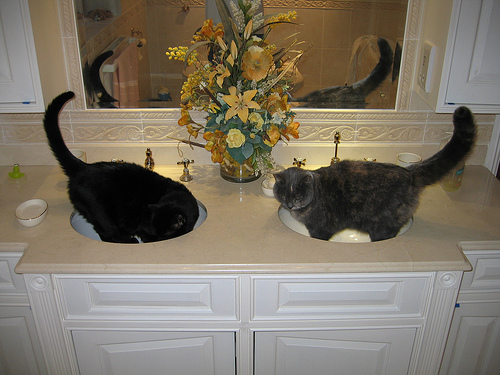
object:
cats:
[41, 89, 202, 244]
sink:
[275, 202, 414, 244]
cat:
[271, 106, 479, 244]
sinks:
[69, 199, 207, 245]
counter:
[0, 151, 500, 274]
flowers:
[224, 127, 247, 151]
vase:
[218, 147, 264, 183]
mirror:
[70, 0, 410, 112]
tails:
[351, 37, 395, 96]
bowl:
[13, 197, 48, 229]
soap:
[23, 203, 39, 218]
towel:
[112, 43, 143, 110]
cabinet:
[443, 0, 500, 104]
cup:
[261, 178, 279, 198]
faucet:
[331, 131, 345, 166]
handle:
[292, 156, 307, 167]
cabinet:
[70, 330, 237, 375]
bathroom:
[0, 0, 500, 374]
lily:
[220, 84, 262, 124]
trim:
[0, 114, 496, 144]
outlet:
[413, 40, 433, 92]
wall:
[350, 120, 392, 156]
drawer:
[250, 276, 434, 322]